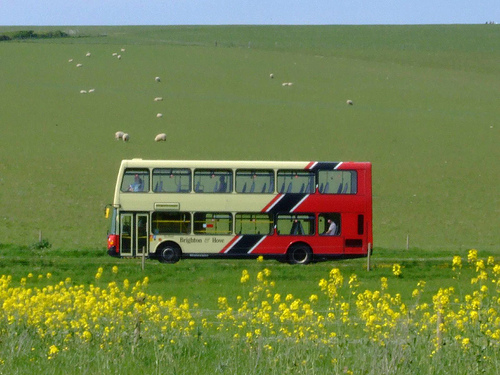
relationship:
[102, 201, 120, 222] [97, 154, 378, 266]
mirror mounted on bus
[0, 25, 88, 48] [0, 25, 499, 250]
bushes inside field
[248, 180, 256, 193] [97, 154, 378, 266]
chair on bus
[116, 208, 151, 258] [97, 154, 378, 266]
door on bus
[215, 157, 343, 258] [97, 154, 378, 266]
stripe on side of bus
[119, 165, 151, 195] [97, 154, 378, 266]
window on top of bus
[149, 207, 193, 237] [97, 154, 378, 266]
window on bottom of bus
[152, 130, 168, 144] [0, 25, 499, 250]
sheep standing in field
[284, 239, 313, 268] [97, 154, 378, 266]
back wheel mounted on bus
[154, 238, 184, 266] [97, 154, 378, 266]
front wheel mounted on bus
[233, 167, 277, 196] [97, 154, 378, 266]
top window mounted on bus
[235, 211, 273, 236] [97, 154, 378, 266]
bottom window mounted on bus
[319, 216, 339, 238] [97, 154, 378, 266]
man riding on bus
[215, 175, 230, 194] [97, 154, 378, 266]
passenger sitting on bus